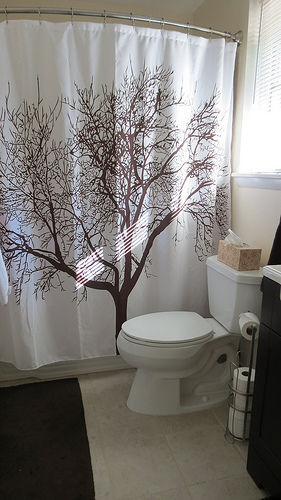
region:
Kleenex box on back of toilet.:
[212, 244, 246, 266]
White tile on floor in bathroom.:
[143, 454, 181, 488]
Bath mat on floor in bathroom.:
[20, 428, 65, 459]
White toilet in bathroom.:
[134, 363, 177, 393]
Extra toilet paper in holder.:
[227, 373, 250, 441]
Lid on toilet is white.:
[141, 316, 182, 335]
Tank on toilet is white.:
[206, 285, 246, 307]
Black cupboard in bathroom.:
[261, 367, 274, 441]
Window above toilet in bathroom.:
[234, 93, 268, 199]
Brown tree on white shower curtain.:
[25, 130, 184, 313]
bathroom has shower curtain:
[1, 5, 240, 371]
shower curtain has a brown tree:
[1, 6, 237, 371]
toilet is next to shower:
[115, 237, 263, 416]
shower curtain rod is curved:
[1, 6, 243, 45]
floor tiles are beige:
[1, 365, 266, 498]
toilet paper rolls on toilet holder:
[224, 310, 259, 442]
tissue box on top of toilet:
[215, 228, 261, 271]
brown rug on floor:
[0, 377, 99, 499]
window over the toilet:
[231, 0, 280, 191]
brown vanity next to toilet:
[243, 265, 279, 498]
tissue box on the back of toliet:
[213, 227, 264, 273]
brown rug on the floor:
[42, 397, 70, 465]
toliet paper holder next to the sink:
[228, 353, 252, 438]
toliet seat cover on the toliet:
[115, 306, 215, 352]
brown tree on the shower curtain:
[3, 55, 211, 300]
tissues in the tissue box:
[223, 226, 246, 248]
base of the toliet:
[131, 387, 175, 413]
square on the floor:
[99, 429, 191, 497]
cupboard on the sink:
[251, 326, 279, 485]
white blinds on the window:
[258, 59, 279, 109]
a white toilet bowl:
[134, 271, 239, 411]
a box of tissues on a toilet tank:
[216, 232, 262, 276]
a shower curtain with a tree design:
[21, 67, 206, 255]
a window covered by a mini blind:
[226, 14, 274, 137]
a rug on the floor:
[51, 398, 103, 480]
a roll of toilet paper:
[234, 310, 260, 342]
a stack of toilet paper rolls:
[229, 359, 249, 442]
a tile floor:
[137, 425, 210, 498]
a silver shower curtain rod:
[0, 3, 241, 22]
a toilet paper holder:
[224, 309, 254, 446]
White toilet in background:
[104, 259, 224, 429]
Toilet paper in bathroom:
[229, 315, 267, 450]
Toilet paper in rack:
[215, 349, 264, 453]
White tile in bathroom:
[94, 423, 233, 493]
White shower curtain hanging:
[31, 9, 223, 67]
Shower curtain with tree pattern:
[13, 6, 205, 297]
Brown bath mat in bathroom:
[5, 382, 123, 497]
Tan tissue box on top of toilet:
[119, 237, 265, 349]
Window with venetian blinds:
[247, 1, 278, 140]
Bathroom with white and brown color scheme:
[5, 3, 275, 497]